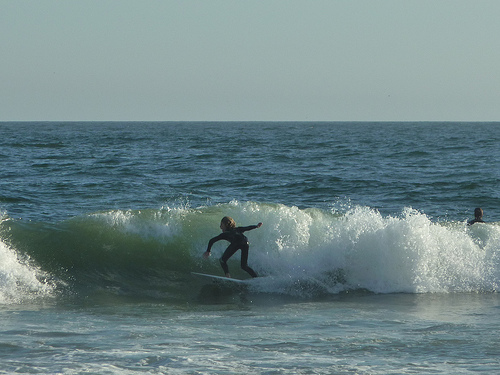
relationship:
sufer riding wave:
[203, 216, 263, 280] [0, 208, 499, 301]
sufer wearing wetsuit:
[203, 216, 263, 280] [208, 224, 259, 278]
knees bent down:
[219, 254, 253, 271] [206, 256, 255, 267]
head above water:
[472, 204, 485, 219] [1, 120, 496, 374]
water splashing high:
[1, 120, 496, 374] [5, 190, 498, 229]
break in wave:
[37, 216, 163, 294] [0, 208, 499, 301]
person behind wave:
[467, 205, 486, 224] [0, 208, 499, 301]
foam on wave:
[231, 199, 497, 287] [0, 208, 499, 301]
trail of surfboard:
[252, 273, 326, 292] [197, 272, 246, 285]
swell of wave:
[93, 209, 327, 268] [0, 208, 499, 301]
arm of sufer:
[239, 223, 265, 233] [203, 216, 263, 280]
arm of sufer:
[203, 234, 224, 256] [203, 216, 263, 280]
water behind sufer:
[0, 307, 498, 375] [203, 216, 263, 280]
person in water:
[467, 205, 486, 224] [1, 120, 496, 374]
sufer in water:
[203, 216, 263, 280] [1, 120, 496, 374]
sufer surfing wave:
[203, 216, 263, 280] [0, 208, 499, 301]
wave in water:
[0, 208, 499, 301] [0, 307, 498, 375]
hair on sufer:
[221, 215, 236, 229] [203, 216, 263, 280]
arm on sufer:
[203, 234, 224, 256] [203, 216, 263, 280]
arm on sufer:
[239, 223, 265, 233] [203, 216, 263, 280]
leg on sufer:
[217, 248, 234, 279] [203, 216, 263, 280]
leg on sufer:
[240, 247, 258, 280] [203, 216, 263, 280]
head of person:
[472, 204, 485, 219] [467, 205, 486, 224]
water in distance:
[4, 120, 499, 203] [3, 119, 499, 186]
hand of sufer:
[203, 251, 213, 257] [203, 216, 263, 280]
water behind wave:
[4, 120, 499, 203] [0, 208, 499, 301]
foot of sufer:
[251, 275, 262, 281] [203, 216, 263, 280]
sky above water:
[3, 1, 500, 124] [0, 307, 498, 375]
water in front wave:
[0, 307, 498, 375] [0, 208, 499, 301]